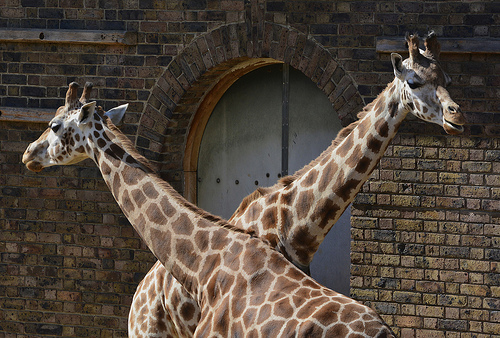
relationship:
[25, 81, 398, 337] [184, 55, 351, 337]
giraffe standing in front of door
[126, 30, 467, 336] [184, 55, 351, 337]
giraffe standing in front of door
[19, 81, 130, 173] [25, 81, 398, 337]
head of giraffe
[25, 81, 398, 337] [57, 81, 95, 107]
giraffe has horns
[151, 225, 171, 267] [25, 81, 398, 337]
spot on giraffe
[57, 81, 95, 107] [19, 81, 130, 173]
horns on head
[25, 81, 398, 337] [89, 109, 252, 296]
giraffe has neck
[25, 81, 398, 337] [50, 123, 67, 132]
giraffe has eye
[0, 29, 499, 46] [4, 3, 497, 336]
line on building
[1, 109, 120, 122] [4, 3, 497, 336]
line on building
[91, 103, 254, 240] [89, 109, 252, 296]
mane on neck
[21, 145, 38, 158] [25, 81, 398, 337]
nose of giraffe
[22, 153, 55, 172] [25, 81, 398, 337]
mouth of giraffe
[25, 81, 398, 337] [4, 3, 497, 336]
giraffe in front of building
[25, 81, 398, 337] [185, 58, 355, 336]
giraffe in front of window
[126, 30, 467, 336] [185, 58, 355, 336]
giraffe in front of window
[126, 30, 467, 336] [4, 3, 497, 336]
giraffe in front of building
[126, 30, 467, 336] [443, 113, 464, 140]
giraffe has mouth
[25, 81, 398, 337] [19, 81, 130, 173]
giraffe has head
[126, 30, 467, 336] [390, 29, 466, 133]
giraffe has head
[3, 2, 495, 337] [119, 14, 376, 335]
wall has archway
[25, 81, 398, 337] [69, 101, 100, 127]
giraffe has ear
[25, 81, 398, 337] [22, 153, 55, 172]
giraffe has mouth